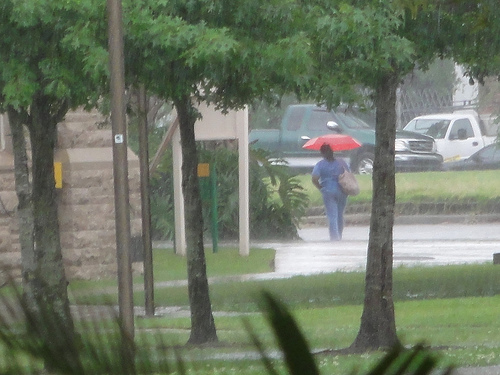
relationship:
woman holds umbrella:
[309, 143, 361, 241] [296, 132, 361, 152]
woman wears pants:
[309, 143, 361, 241] [320, 189, 349, 235]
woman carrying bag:
[309, 143, 361, 241] [336, 164, 357, 197]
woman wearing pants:
[309, 143, 361, 241] [322, 188, 343, 239]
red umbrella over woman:
[302, 133, 361, 152] [309, 143, 361, 241]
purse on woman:
[341, 166, 356, 196] [309, 143, 361, 241]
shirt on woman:
[306, 154, 354, 196] [309, 141, 347, 241]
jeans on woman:
[313, 178, 354, 240] [309, 140, 355, 240]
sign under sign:
[193, 162, 213, 179] [167, 94, 244, 139]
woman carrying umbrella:
[309, 143, 361, 241] [303, 132, 383, 154]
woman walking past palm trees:
[309, 143, 361, 241] [194, 143, 310, 238]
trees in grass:
[314, 13, 444, 365] [0, 260, 491, 368]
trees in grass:
[146, 7, 242, 354] [0, 260, 491, 368]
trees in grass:
[3, 2, 106, 327] [0, 260, 491, 368]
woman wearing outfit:
[309, 143, 361, 241] [316, 158, 350, 235]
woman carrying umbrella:
[309, 143, 361, 241] [300, 132, 366, 156]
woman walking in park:
[306, 139, 350, 239] [166, 135, 498, 305]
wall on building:
[58, 162, 113, 269] [0, 64, 156, 298]